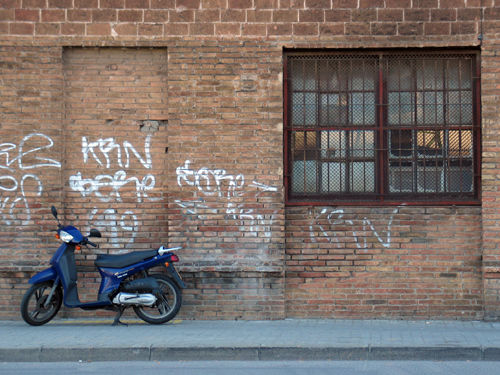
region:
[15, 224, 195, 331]
the bike is blue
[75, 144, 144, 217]
white writing is on the wall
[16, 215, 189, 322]
the bike isparked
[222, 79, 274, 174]
the wall is brown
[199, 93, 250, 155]
the wall has bricks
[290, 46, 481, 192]
the window has bars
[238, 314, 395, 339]
the pavement is grey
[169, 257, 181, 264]
the tail lights re red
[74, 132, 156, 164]
KRN IS ON THE WALL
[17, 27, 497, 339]
a moped by wall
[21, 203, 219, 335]
a blue motorcycle in the picture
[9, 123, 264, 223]
white graffiti on a wall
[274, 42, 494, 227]
a window in the building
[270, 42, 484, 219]
this window is missing some panes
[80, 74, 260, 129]
brown bricks on the building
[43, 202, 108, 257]
a light on the moped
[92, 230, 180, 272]
the seat is black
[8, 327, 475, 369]
a curb near the building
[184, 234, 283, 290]
white paint runoff on the building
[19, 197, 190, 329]
the mo-ped on the sidewalk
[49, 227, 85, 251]
the light on the bike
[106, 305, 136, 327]
the black kickstandon the ground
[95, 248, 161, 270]
the black seat of the bike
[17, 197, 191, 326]
the blue bike by the wall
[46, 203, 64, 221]
the black sideview mirror on the mo-ped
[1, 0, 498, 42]
the white lines in the bricks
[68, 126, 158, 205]
the white writing on the wall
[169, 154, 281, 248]
the white graffitti on the brick wall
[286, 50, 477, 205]
the mesh wire behind the walls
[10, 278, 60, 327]
wheel of bike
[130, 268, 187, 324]
wheel of a bike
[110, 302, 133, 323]
handle of a bike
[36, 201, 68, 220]
mirror of a bike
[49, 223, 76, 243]
lights of a bike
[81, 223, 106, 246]
wheel of a bike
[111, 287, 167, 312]
exhaust of a bike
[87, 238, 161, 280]
seat of a bike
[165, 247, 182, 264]
tail light of a bike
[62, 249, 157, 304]
body of a bike